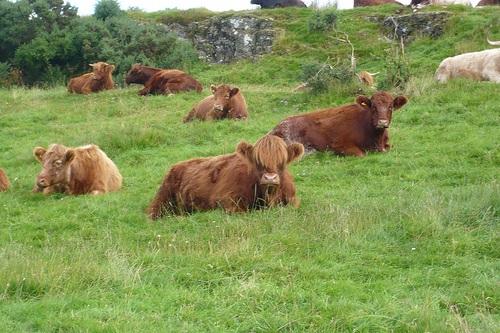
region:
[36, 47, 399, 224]
Cows laying down in a field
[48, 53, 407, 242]
The cows are on top of grass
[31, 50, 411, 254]
The cows are brown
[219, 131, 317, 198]
The cow has thick hair over its eyes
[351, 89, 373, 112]
The cow has a yellow tag on its ear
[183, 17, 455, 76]
Rocky ledge with grass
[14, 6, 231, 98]
Dark green bushes behind the cows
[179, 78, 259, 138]
The cow is on its side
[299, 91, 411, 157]
The cow is looking at the camera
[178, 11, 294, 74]
The rocks are grey and white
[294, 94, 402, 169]
big dark brown cow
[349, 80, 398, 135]
face of the sheep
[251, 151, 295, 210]
angry face of the animal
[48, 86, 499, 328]
a beautiful view of grass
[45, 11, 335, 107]
group of trees on back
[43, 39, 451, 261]
a group of animals sitting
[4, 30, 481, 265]
group of sheeps sitting in grass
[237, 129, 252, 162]
ear of the sheep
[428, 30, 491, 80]
a white cow sitting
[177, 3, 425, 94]
a stone type wall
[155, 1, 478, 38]
building present back side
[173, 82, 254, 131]
Brown cow laying in grass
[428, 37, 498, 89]
Tan bull on far right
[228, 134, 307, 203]
Cow with hair covering eyes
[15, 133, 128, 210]
Brown cow laying on the grass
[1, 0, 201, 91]
Group of trees in background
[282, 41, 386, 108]
Bush covering cow on grass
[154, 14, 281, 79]
Stone wall on hill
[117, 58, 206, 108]
Brown cow on grass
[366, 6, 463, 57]
Large rock on hill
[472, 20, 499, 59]
Horn on tan bull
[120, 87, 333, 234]
the cow is brown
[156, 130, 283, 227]
the cow is brown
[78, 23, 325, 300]
the cow is brown